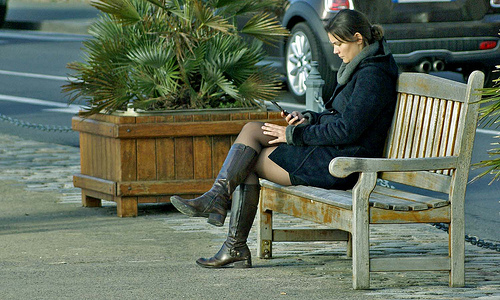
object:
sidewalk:
[0, 122, 480, 297]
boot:
[170, 143, 260, 227]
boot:
[196, 184, 261, 268]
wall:
[403, 168, 435, 184]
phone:
[270, 100, 300, 123]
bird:
[170, 9, 399, 268]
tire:
[282, 21, 336, 105]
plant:
[61, 0, 295, 116]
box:
[71, 112, 289, 218]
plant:
[467, 65, 500, 184]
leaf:
[199, 61, 240, 103]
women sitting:
[169, 7, 409, 268]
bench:
[272, 60, 469, 288]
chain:
[0, 114, 73, 133]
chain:
[429, 222, 500, 252]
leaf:
[239, 10, 292, 48]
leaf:
[69, 68, 120, 94]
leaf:
[125, 44, 171, 69]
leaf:
[138, 70, 171, 97]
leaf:
[88, 1, 141, 27]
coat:
[267, 52, 398, 190]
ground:
[0, 26, 500, 300]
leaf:
[235, 65, 283, 105]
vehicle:
[208, 0, 500, 104]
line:
[0, 93, 88, 115]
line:
[0, 69, 500, 136]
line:
[0, 28, 94, 42]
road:
[2, 28, 499, 247]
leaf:
[189, 0, 235, 36]